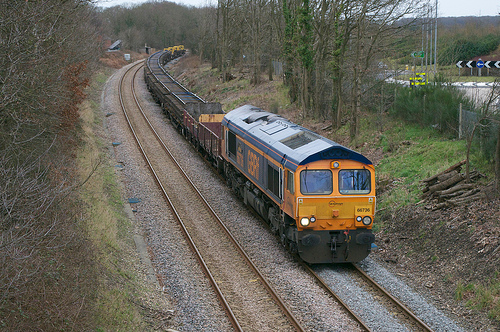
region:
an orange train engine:
[220, 100, 375, 261]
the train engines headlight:
[300, 215, 310, 226]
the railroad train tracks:
[116, 55, 168, 160]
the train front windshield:
[297, 166, 332, 192]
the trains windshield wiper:
[301, 162, 308, 189]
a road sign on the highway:
[455, 57, 496, 67]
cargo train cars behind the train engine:
[140, 40, 217, 160]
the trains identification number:
[240, 146, 260, 181]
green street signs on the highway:
[410, 48, 425, 58]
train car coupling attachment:
[326, 230, 354, 258]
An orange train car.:
[193, 78, 390, 277]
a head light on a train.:
[289, 203, 317, 244]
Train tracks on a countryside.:
[107, 37, 440, 329]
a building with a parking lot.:
[321, 0, 494, 113]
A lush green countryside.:
[0, 0, 165, 327]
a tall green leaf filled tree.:
[344, 0, 426, 138]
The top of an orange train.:
[220, 75, 371, 167]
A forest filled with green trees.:
[101, 0, 221, 61]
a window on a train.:
[255, 146, 285, 207]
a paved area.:
[429, 82, 496, 114]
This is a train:
[219, 99, 388, 287]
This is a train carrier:
[183, 91, 225, 187]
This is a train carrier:
[162, 79, 186, 136]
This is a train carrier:
[153, 73, 168, 120]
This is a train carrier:
[136, 61, 166, 95]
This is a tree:
[348, 4, 375, 146]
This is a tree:
[326, 11, 351, 138]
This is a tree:
[307, 4, 332, 129]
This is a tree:
[292, 9, 320, 119]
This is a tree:
[278, 4, 298, 104]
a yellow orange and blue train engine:
[223, 100, 378, 267]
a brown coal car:
[198, 118, 223, 167]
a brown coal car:
[184, 101, 224, 137]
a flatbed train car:
[161, 90, 205, 130]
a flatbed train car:
[152, 79, 190, 102]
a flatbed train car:
[145, 72, 173, 89]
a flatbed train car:
[143, 65, 164, 80]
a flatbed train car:
[145, 56, 167, 66]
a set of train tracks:
[301, 254, 433, 330]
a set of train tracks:
[118, 57, 300, 329]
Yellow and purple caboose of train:
[199, 95, 376, 232]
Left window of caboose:
[295, 161, 335, 196]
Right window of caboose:
[335, 163, 368, 196]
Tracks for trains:
[116, 37, 298, 328]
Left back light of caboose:
[293, 213, 313, 233]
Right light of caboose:
[358, 212, 375, 225]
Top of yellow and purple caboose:
[221, 100, 370, 162]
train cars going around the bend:
[138, 32, 220, 110]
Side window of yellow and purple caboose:
[248, 142, 289, 211]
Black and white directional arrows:
[452, 57, 497, 69]